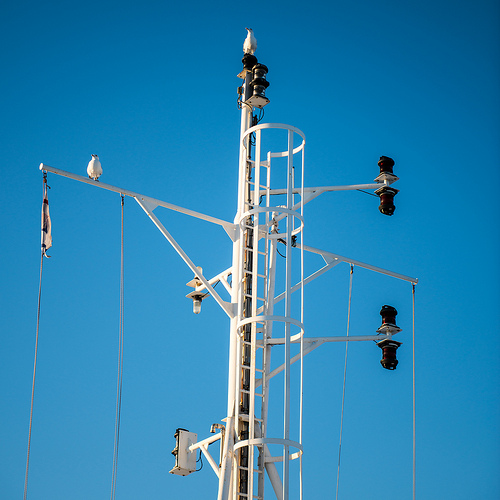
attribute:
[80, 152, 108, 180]
bird — white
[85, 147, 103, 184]
bird — white 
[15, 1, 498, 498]
sky — blue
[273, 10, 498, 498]
sky — blue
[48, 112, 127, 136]
clouds — white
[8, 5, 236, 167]
sky — blue 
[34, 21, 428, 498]
tower — white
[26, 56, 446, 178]
clouds — white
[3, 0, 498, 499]
blue sky — blue 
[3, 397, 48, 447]
blue — sky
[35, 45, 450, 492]
sky — blue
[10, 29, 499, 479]
sky — blue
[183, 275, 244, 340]
bulb — clear, glass, light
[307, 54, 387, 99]
clouds — white 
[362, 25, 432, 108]
clouds — white